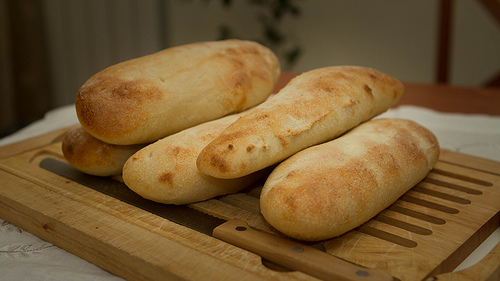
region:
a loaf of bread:
[254, 112, 441, 244]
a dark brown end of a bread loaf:
[66, 71, 102, 133]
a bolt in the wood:
[233, 219, 251, 236]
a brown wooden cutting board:
[1, 107, 496, 279]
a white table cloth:
[1, 98, 499, 279]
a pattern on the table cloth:
[0, 236, 62, 262]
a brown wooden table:
[268, 65, 499, 121]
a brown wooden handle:
[208, 210, 400, 280]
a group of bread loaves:
[46, 32, 450, 245]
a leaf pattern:
[3, 238, 21, 254]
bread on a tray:
[67, 10, 449, 258]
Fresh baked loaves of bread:
[68, 42, 439, 230]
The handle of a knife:
[204, 219, 315, 279]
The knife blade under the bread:
[36, 148, 216, 237]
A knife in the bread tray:
[17, 151, 381, 277]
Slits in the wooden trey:
[427, 147, 464, 278]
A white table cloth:
[447, 108, 487, 150]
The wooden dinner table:
[427, 81, 499, 111]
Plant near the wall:
[225, 3, 304, 42]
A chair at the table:
[428, 8, 498, 94]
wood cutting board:
[2, 118, 499, 278]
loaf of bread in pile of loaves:
[259, 115, 441, 240]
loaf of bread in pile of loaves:
[195, 62, 405, 177]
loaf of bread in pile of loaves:
[120, 110, 272, 204]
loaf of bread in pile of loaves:
[73, 37, 280, 143]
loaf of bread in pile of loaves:
[62, 126, 134, 176]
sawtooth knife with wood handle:
[37, 156, 395, 279]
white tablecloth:
[0, 98, 498, 279]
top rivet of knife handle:
[233, 221, 250, 235]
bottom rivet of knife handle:
[354, 267, 371, 279]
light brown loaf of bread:
[274, 108, 459, 233]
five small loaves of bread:
[61, 36, 441, 241]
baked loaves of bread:
[61, 36, 438, 241]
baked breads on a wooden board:
[61, 38, 442, 244]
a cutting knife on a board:
[37, 155, 397, 280]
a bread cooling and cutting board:
[0, 120, 498, 280]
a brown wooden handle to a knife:
[215, 218, 396, 279]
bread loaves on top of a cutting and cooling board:
[0, 37, 498, 279]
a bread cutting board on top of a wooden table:
[0, 37, 498, 279]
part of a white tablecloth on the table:
[440, 105, 499, 148]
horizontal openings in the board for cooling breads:
[433, 163, 495, 218]